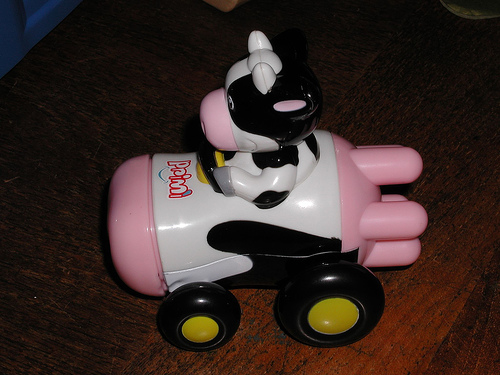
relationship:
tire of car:
[153, 282, 244, 356] [95, 23, 436, 355]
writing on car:
[162, 154, 195, 204] [95, 23, 440, 343]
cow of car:
[188, 25, 331, 210] [95, 23, 440, 343]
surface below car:
[4, 0, 497, 371] [95, 23, 436, 355]